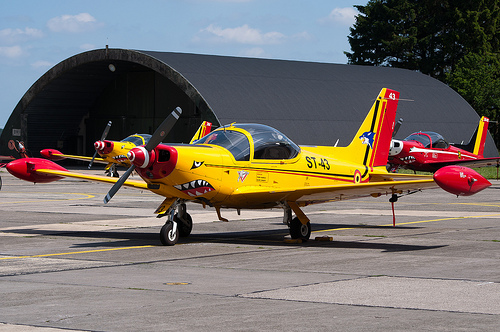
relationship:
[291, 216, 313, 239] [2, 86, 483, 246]
back wheel of flight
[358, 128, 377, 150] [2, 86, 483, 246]
logo of flight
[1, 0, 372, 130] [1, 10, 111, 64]
sky with clouds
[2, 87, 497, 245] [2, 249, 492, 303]
flight on a pavement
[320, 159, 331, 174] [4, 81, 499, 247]
number on plane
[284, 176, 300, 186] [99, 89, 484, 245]
yellow and red plane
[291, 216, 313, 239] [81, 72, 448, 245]
back wheel of yellow plane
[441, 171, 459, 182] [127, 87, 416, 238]
red white and yellow plane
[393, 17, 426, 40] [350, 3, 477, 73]
dark green tall trees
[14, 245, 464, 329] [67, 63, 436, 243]
ground pavement for plane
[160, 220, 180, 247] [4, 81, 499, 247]
front wheel mounted on plane